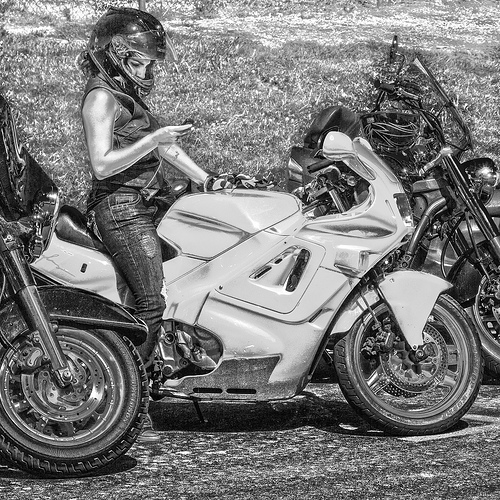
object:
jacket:
[80, 82, 168, 202]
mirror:
[320, 129, 356, 164]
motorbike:
[302, 28, 499, 383]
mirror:
[385, 34, 405, 72]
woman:
[63, 7, 225, 393]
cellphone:
[180, 117, 194, 130]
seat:
[54, 204, 109, 255]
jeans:
[87, 190, 170, 366]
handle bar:
[305, 157, 341, 175]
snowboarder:
[78, 84, 186, 202]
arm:
[82, 89, 155, 181]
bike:
[26, 105, 481, 438]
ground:
[407, 153, 443, 194]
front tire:
[0, 320, 152, 472]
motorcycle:
[0, 146, 141, 484]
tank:
[143, 173, 308, 259]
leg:
[94, 177, 171, 394]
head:
[74, 3, 167, 102]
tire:
[333, 276, 482, 438]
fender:
[373, 267, 455, 352]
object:
[177, 110, 199, 140]